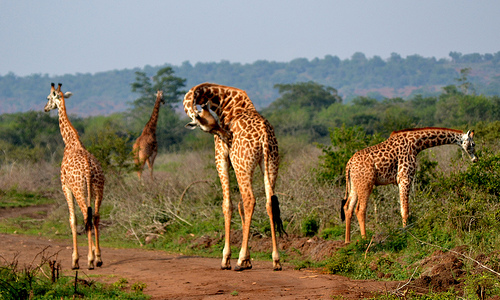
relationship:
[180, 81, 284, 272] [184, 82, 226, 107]
giraffe bending neck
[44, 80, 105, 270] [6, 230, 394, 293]
giraffe on dirt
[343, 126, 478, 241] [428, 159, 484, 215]
giraffe eating grass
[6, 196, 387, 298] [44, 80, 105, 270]
trail with giraffe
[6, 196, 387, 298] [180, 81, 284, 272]
trail with giraffe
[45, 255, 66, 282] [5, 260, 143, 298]
twig in grass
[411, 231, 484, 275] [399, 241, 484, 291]
stick next to dirt